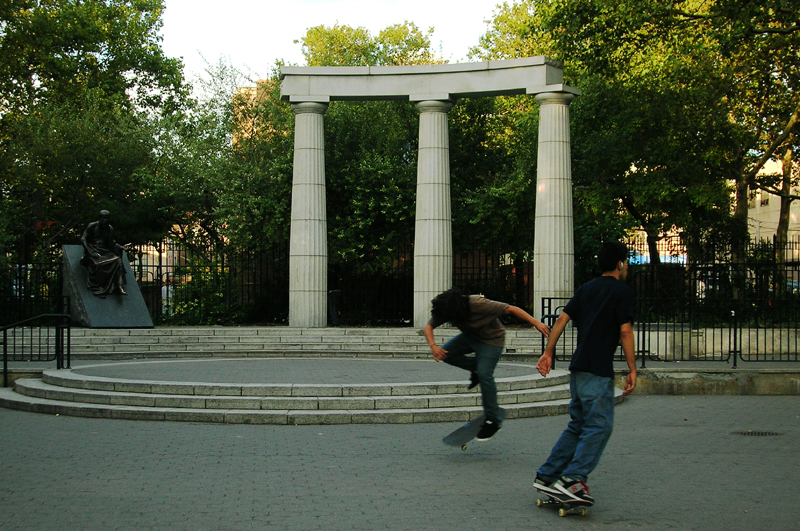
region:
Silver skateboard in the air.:
[436, 390, 520, 451]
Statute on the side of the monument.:
[61, 189, 152, 323]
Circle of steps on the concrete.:
[25, 362, 493, 437]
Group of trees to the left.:
[34, 19, 187, 217]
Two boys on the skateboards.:
[406, 225, 655, 526]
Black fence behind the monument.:
[669, 237, 783, 351]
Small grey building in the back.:
[745, 166, 797, 271]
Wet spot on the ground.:
[377, 351, 447, 387]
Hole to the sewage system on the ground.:
[710, 415, 785, 433]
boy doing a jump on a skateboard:
[420, 287, 552, 452]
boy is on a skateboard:
[532, 238, 642, 518]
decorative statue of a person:
[78, 207, 142, 307]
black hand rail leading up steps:
[6, 308, 76, 392]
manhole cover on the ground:
[730, 423, 786, 442]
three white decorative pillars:
[276, 56, 577, 330]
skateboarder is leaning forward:
[532, 235, 639, 519]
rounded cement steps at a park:
[5, 379, 632, 432]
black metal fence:
[628, 229, 797, 371]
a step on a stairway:
[4, 384, 632, 418]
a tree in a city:
[5, 3, 186, 310]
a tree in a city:
[213, 21, 464, 304]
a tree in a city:
[533, 7, 787, 317]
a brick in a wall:
[238, 331, 283, 341]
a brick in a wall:
[324, 332, 373, 359]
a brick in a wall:
[388, 337, 418, 355]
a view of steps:
[169, 330, 338, 453]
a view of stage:
[116, 317, 615, 432]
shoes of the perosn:
[498, 453, 610, 513]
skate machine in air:
[429, 392, 520, 445]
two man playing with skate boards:
[325, 161, 714, 510]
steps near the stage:
[229, 339, 344, 455]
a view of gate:
[7, 248, 104, 404]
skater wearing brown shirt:
[414, 277, 539, 430]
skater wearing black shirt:
[538, 233, 643, 499]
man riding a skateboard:
[539, 239, 667, 512]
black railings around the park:
[17, 234, 794, 363]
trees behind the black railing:
[8, 4, 792, 298]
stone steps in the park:
[9, 351, 625, 429]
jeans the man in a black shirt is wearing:
[534, 373, 624, 487]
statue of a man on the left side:
[82, 203, 135, 296]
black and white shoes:
[459, 360, 502, 443]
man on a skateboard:
[538, 236, 639, 509]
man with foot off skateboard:
[420, 289, 553, 452]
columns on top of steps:
[0, 56, 600, 354]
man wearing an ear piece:
[534, 239, 640, 515]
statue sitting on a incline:
[54, 208, 153, 329]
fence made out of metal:
[4, 241, 797, 382]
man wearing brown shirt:
[420, 288, 550, 452]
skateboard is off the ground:
[2, 391, 798, 528]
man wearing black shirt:
[536, 236, 634, 514]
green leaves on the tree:
[635, 183, 665, 209]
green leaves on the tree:
[497, 178, 548, 242]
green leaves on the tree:
[354, 248, 379, 264]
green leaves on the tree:
[380, 167, 424, 229]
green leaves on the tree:
[213, 240, 270, 329]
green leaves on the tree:
[69, 168, 131, 217]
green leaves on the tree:
[105, 98, 165, 195]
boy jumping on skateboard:
[400, 248, 563, 433]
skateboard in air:
[432, 398, 521, 460]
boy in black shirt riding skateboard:
[529, 216, 670, 498]